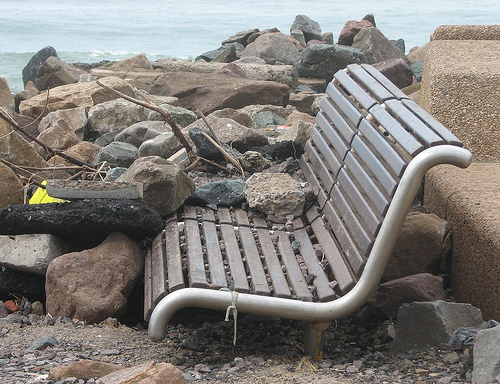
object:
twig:
[20, 165, 84, 170]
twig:
[0, 110, 93, 169]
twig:
[201, 131, 246, 180]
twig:
[184, 155, 235, 175]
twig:
[196, 108, 232, 165]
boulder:
[292, 44, 368, 80]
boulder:
[240, 32, 300, 65]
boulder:
[148, 72, 290, 120]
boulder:
[21, 46, 61, 91]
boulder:
[44, 233, 144, 325]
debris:
[0, 312, 500, 384]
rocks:
[78, 70, 268, 208]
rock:
[45, 229, 145, 324]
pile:
[9, 62, 319, 181]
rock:
[381, 212, 452, 282]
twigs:
[67, 170, 84, 181]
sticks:
[94, 80, 244, 176]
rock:
[28, 118, 80, 161]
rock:
[188, 126, 243, 166]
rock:
[238, 28, 305, 65]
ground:
[1, 301, 461, 381]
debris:
[29, 180, 71, 205]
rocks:
[388, 300, 480, 361]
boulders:
[87, 97, 149, 136]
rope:
[225, 290, 238, 346]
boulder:
[296, 44, 368, 83]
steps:
[428, 62, 475, 117]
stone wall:
[419, 24, 500, 332]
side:
[149, 144, 473, 358]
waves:
[70, 40, 136, 57]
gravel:
[8, 301, 474, 376]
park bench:
[143, 63, 473, 362]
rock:
[471, 325, 500, 384]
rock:
[194, 178, 255, 204]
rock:
[273, 120, 310, 149]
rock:
[205, 108, 273, 151]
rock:
[139, 72, 290, 114]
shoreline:
[2, 2, 492, 123]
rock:
[240, 170, 305, 222]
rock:
[371, 273, 447, 321]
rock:
[112, 156, 195, 218]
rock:
[242, 151, 270, 175]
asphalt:
[0, 199, 165, 245]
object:
[0, 272, 36, 323]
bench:
[144, 63, 474, 363]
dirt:
[124, 347, 176, 359]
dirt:
[5, 323, 125, 340]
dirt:
[247, 367, 347, 382]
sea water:
[0, 2, 495, 64]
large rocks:
[44, 232, 144, 325]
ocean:
[14, 3, 236, 29]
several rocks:
[19, 69, 322, 216]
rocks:
[16, 24, 306, 221]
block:
[417, 38, 500, 163]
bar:
[182, 219, 208, 288]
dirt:
[66, 320, 191, 366]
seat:
[140, 169, 336, 341]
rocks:
[327, 322, 475, 382]